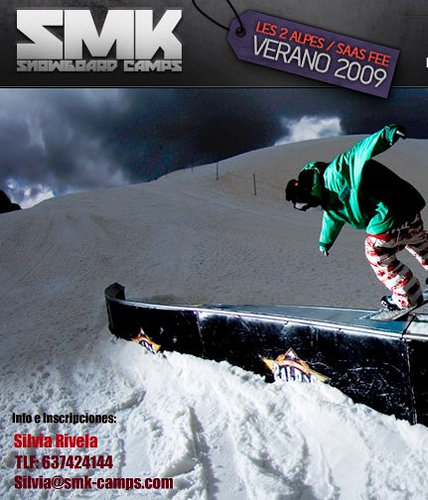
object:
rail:
[103, 280, 427, 430]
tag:
[227, 0, 424, 101]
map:
[149, 389, 267, 447]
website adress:
[11, 472, 175, 490]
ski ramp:
[104, 278, 426, 426]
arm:
[352, 121, 406, 167]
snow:
[0, 135, 427, 499]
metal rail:
[104, 282, 427, 433]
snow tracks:
[170, 405, 339, 499]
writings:
[8, 410, 174, 491]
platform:
[102, 280, 424, 426]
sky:
[0, 88, 426, 210]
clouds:
[0, 86, 426, 211]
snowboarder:
[283, 121, 427, 313]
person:
[285, 123, 428, 311]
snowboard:
[369, 283, 427, 322]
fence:
[164, 150, 323, 213]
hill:
[0, 134, 426, 498]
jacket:
[297, 125, 426, 256]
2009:
[333, 57, 388, 89]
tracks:
[0, 183, 425, 498]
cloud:
[274, 111, 342, 146]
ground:
[0, 132, 426, 498]